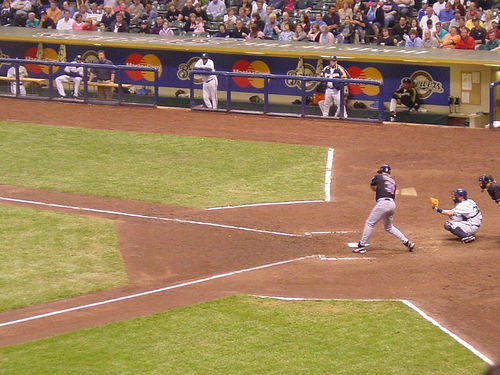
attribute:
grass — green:
[0, 121, 333, 208]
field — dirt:
[131, 200, 484, 314]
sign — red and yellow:
[235, 61, 270, 87]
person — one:
[437, 24, 469, 43]